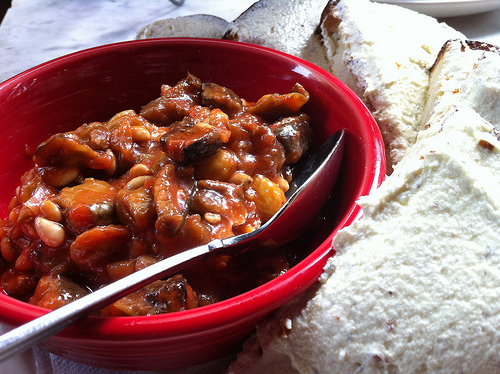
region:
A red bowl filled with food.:
[26, 43, 272, 217]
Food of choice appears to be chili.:
[26, 140, 239, 235]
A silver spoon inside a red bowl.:
[235, 105, 396, 250]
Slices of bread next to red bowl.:
[318, 3, 498, 122]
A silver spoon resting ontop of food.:
[208, 106, 341, 250]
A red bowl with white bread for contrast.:
[109, 30, 412, 78]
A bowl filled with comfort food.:
[15, 70, 280, 205]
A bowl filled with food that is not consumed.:
[90, 93, 317, 238]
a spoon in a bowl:
[12, 1, 476, 359]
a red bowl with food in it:
[21, 13, 392, 343]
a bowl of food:
[37, 15, 394, 285]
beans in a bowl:
[32, 6, 432, 361]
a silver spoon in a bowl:
[47, 32, 444, 360]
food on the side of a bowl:
[222, 2, 454, 349]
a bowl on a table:
[7, 1, 419, 349]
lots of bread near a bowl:
[188, 6, 498, 337]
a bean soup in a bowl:
[24, 3, 456, 328]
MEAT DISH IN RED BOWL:
[1, 22, 410, 354]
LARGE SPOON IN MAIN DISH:
[3, 122, 361, 355]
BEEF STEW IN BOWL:
[12, 82, 294, 323]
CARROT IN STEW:
[61, 221, 144, 273]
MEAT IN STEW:
[147, 114, 244, 175]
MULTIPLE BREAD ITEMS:
[266, 18, 485, 350]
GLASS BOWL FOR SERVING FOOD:
[10, 37, 379, 360]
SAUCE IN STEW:
[29, 71, 305, 284]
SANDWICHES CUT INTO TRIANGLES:
[308, 4, 482, 255]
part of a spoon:
[91, 298, 111, 311]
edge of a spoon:
[118, 283, 135, 308]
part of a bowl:
[236, 304, 258, 331]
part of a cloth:
[361, 240, 371, 262]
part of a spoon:
[286, 200, 302, 227]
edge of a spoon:
[193, 243, 194, 250]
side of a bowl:
[228, 333, 250, 345]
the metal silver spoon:
[19, 118, 318, 346]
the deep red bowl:
[27, 40, 387, 350]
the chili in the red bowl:
[4, 80, 336, 297]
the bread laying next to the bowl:
[157, 4, 489, 359]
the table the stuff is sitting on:
[9, 7, 291, 50]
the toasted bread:
[183, 11, 498, 364]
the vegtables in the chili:
[11, 94, 265, 289]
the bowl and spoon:
[14, 26, 323, 357]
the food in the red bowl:
[15, 61, 331, 328]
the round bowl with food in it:
[26, 38, 336, 343]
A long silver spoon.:
[0, 127, 347, 365]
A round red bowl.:
[1, 36, 387, 370]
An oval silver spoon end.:
[257, 127, 347, 252]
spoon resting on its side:
[0, 135, 345, 368]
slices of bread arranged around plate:
[147, 11, 495, 368]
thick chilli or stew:
[1, 78, 295, 320]